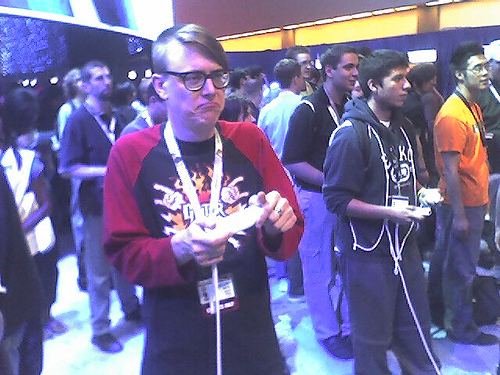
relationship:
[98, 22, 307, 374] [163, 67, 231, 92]
man wearing glasses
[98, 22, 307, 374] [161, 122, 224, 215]
man wearing lanyard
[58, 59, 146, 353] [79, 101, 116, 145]
man wearing lanyard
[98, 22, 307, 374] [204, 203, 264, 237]
man holding controller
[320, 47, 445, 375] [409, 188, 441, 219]
man holding controller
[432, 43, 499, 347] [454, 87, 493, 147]
man has camera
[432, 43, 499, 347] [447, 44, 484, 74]
man has hair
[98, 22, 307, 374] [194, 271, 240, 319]
man has tag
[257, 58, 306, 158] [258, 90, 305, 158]
man wearing shirt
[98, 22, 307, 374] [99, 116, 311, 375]
man wearing shirt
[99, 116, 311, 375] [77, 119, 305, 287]
shirt has sleeves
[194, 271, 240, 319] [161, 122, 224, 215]
tag on lanyard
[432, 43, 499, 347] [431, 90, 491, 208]
man wearing shirt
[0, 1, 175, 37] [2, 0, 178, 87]
light across wall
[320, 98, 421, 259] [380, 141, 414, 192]
hoodie has print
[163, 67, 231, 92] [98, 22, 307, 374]
glasses on man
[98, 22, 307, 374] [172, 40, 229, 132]
man has face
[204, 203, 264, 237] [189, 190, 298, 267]
controller in hands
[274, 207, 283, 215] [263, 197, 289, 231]
ring on a finger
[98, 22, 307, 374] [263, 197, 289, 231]
man has finger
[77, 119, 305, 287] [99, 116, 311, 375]
sleeves on shirt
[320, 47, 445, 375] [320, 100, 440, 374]
man wearing clothing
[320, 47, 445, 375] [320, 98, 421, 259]
man has hoodie